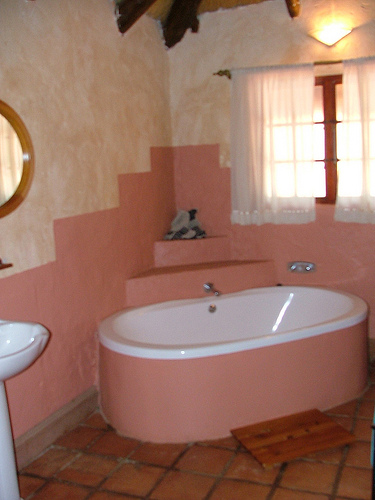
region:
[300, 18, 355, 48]
Light fixture attached to wall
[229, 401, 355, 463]
Wood board on floor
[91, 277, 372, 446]
Deep pink and white bathtub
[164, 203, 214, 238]
Wad of dirty clothes in corner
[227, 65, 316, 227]
Sheer white bathroom window curtain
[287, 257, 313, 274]
Hot and cold water knobs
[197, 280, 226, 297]
Chrome water spout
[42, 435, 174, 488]
Brown floor tiles in need of repair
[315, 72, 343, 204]
Wood frame of bathroom window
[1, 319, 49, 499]
Porcelain pedestal sink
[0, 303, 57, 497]
White porcelain bathroom sink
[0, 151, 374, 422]
Pink walls and tub surround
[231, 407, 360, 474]
Orange floor mat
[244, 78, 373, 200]
Light shining through window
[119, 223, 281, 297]
Step out bathtub shelves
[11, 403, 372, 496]
Stained floor tile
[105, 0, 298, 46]
Brown wooden ceiling beams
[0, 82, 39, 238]
Wood trimmed bathroom mirror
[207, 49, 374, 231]
White curtains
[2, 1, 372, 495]
Picture is out of focus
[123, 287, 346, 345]
the bath tub is white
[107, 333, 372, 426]
the tub enclosure is pink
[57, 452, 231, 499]
the floor is brown tile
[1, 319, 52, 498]
The pedestal sink is white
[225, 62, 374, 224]
the window curtains are white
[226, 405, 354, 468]
a wooden step to the bath tub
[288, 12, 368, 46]
a light on the wall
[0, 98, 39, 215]
a mirror on the wall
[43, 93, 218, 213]
the walls are two different colors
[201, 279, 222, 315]
the tub faucet is silver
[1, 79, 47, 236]
Part of a wood framed mirror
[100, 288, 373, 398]
Pink and white bathtub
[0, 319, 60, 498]
White pedestal sink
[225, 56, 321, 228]
White curtain hanging in window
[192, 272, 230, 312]
Silver tap for bathtub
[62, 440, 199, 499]
Brown tiled floor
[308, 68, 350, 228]
Brown window pane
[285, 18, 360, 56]
Light fixture on wall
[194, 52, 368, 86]
Curtain rod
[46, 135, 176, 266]
Pink painted stair steps on wall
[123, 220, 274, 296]
A two-step shelf in a corner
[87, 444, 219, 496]
A brown tile floor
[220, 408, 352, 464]
A wooden step up to a bath tub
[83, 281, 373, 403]
A white bathtub in a pink foundation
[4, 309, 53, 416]
A white pedestal sink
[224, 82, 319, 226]
White curtains in a window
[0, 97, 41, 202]
A round mirror over a sink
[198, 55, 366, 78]
A curtain rod over a window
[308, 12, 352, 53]
A light over a window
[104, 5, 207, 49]
Roof support beams